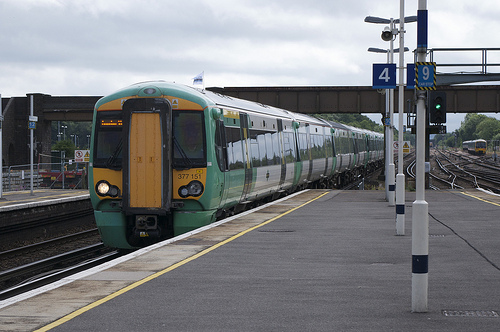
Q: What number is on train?
A: 377151.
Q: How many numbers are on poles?
A: 2.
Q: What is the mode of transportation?
A: Train.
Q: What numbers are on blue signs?
A: 4, 9.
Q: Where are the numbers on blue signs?
A: The poles.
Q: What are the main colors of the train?
A: Green and yellow.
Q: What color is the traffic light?
A: Green.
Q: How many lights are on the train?
A: One.